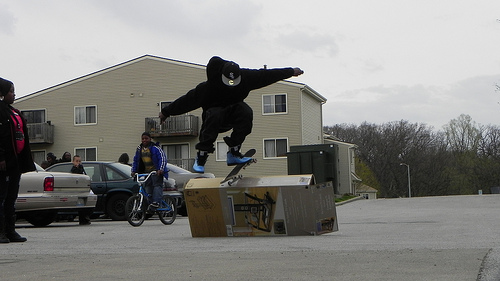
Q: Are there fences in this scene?
A: No, there are no fences.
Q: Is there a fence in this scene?
A: No, there are no fences.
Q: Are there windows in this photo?
A: Yes, there is a window.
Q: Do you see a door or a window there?
A: Yes, there is a window.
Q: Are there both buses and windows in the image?
A: No, there is a window but no buses.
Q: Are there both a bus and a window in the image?
A: No, there is a window but no buses.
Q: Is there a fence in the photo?
A: No, there are no fences.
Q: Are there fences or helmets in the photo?
A: No, there are no fences or helmets.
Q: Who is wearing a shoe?
A: The man is wearing a shoe.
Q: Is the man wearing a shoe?
A: Yes, the man is wearing a shoe.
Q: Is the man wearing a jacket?
A: No, the man is wearing a shoe.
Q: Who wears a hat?
A: The man wears a hat.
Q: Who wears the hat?
A: The man wears a hat.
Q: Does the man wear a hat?
A: Yes, the man wears a hat.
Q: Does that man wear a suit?
A: No, the man wears a hat.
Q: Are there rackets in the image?
A: No, there are no rackets.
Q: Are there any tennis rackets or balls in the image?
A: No, there are no tennis rackets or balls.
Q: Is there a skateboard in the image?
A: Yes, there is a skateboard.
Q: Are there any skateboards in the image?
A: Yes, there is a skateboard.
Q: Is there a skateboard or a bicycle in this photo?
A: Yes, there is a skateboard.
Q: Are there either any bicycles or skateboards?
A: Yes, there is a skateboard.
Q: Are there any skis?
A: No, there are no skis.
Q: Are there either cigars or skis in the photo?
A: No, there are no skis or cigars.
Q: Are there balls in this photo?
A: No, there are no balls.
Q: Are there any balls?
A: No, there are no balls.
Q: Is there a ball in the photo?
A: No, there are no balls.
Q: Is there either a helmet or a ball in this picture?
A: No, there are no balls or helmets.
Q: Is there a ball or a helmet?
A: No, there are no balls or helmets.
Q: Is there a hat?
A: Yes, there is a hat.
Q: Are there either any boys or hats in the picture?
A: Yes, there is a hat.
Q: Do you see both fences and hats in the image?
A: No, there is a hat but no fences.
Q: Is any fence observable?
A: No, there are no fences.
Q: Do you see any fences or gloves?
A: No, there are no fences or gloves.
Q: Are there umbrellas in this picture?
A: No, there are no umbrellas.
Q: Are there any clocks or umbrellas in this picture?
A: No, there are no umbrellas or clocks.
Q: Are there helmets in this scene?
A: No, there are no helmets.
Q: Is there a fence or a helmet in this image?
A: No, there are no helmets or fences.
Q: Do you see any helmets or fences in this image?
A: No, there are no helmets or fences.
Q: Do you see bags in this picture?
A: No, there are no bags.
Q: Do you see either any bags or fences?
A: No, there are no bags or fences.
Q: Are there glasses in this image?
A: No, there are no glasses.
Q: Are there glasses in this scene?
A: No, there are no glasses.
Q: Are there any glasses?
A: No, there are no glasses.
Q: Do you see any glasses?
A: No, there are no glasses.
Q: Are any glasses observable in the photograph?
A: No, there are no glasses.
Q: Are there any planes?
A: No, there are no planes.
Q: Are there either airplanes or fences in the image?
A: No, there are no airplanes or fences.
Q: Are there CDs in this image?
A: No, there are no cds.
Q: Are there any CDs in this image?
A: No, there are no cds.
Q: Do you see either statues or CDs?
A: No, there are no CDs or statues.